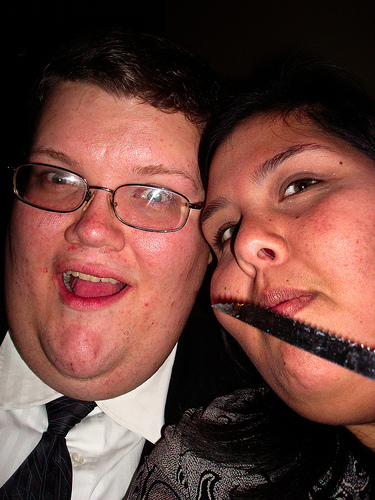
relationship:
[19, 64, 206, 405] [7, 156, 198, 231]
man wearing glasses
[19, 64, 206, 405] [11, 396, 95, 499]
man wearing tie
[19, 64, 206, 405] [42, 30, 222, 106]
man has hair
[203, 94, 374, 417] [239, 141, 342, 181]
woman has eyebrow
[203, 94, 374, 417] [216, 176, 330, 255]
woman has eyes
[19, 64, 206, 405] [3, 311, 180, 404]
man has double chin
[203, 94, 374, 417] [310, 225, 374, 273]
woman has freckles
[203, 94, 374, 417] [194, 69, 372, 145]
woman has hair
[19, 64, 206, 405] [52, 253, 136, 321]
man has mouth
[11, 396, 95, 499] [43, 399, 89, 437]
tie has knot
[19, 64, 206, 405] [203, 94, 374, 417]
man beside woman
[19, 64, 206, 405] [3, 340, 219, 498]
man wearing suit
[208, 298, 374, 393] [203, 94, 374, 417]
knife blade in front of woman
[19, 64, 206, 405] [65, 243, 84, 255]
man has acne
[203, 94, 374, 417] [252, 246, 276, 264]
woman has nostril